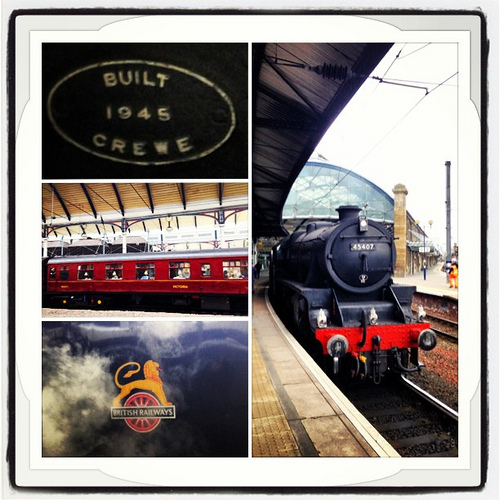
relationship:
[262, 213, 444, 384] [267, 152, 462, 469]
train at station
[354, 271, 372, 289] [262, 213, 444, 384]
logo on train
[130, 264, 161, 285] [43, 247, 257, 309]
window of train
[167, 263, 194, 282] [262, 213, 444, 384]
window of train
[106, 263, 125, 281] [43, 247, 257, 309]
window of train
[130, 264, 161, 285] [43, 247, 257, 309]
window of a train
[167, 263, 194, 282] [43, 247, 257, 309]
window of a train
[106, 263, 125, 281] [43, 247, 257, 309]
window of a train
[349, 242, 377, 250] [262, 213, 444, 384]
numbers on train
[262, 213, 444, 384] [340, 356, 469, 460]
train on tracks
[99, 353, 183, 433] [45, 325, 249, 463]
lion on train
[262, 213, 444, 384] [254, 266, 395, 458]
train next to platform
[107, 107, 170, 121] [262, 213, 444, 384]
date of train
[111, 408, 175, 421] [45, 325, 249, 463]
name of train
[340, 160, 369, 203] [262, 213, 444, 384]
steam coming from train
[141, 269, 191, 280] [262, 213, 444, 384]
people on train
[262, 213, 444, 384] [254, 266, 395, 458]
train passing platform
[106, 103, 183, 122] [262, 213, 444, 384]
date of train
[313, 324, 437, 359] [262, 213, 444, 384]
bumper of train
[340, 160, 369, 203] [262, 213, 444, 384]
steam from train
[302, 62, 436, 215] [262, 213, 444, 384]
power lines above train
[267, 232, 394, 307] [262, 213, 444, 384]
engine of a train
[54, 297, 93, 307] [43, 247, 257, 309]
wheel of a train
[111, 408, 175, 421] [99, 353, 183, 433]
name below lion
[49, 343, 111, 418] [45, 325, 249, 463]
clouds reflected on train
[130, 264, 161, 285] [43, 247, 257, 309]
window on train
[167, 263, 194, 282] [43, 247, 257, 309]
window on train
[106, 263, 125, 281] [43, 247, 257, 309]
window on train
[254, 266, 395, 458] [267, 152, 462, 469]
platform at station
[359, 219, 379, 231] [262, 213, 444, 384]
headlight on train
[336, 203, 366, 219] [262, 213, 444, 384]
smoke stack on train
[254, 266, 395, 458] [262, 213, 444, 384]
platform beside train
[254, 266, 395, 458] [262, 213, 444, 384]
platform next to train